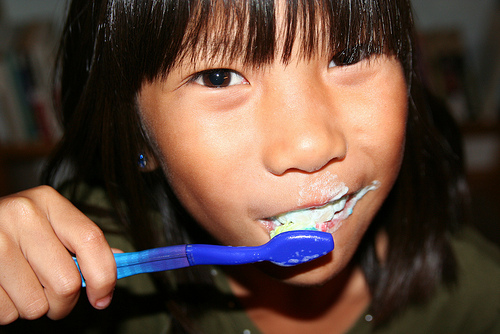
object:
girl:
[2, 1, 500, 330]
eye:
[191, 67, 251, 88]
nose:
[263, 73, 346, 175]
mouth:
[256, 186, 364, 238]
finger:
[49, 195, 117, 310]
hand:
[1, 185, 119, 326]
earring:
[137, 149, 147, 169]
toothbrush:
[71, 230, 335, 288]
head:
[71, 0, 410, 291]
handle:
[71, 244, 193, 287]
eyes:
[326, 43, 381, 71]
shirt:
[1, 173, 500, 334]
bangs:
[123, 0, 404, 93]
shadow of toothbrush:
[113, 282, 261, 318]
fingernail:
[95, 293, 113, 308]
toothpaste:
[265, 176, 382, 234]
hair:
[36, 1, 473, 332]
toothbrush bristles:
[267, 219, 313, 239]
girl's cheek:
[343, 74, 407, 194]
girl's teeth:
[311, 202, 338, 222]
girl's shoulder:
[8, 180, 499, 334]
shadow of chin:
[222, 264, 358, 320]